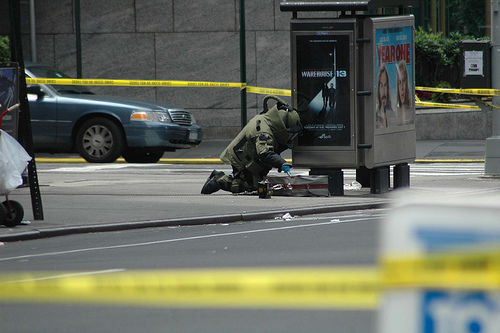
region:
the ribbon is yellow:
[25, 62, 296, 103]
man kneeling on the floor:
[194, 97, 328, 207]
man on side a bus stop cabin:
[194, 0, 428, 207]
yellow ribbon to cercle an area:
[0, 72, 499, 318]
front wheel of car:
[74, 110, 127, 170]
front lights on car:
[151, 107, 201, 129]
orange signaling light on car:
[125, 104, 155, 124]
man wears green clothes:
[199, 102, 314, 204]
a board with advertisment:
[360, 10, 422, 172]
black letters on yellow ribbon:
[23, 70, 290, 102]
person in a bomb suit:
[199, 93, 309, 208]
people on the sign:
[377, 56, 415, 128]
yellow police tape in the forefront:
[2, 249, 497, 321]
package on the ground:
[262, 167, 331, 204]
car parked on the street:
[22, 58, 207, 165]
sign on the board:
[287, 15, 354, 163]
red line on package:
[283, 180, 332, 189]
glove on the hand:
[267, 148, 287, 173]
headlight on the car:
[150, 107, 171, 126]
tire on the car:
[70, 110, 126, 166]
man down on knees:
[194, 88, 309, 203]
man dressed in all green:
[187, 90, 309, 196]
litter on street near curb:
[255, 205, 299, 223]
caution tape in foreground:
[4, 244, 499, 314]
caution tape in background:
[25, 66, 497, 106]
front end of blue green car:
[17, 59, 205, 162]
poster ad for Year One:
[370, 23, 418, 137]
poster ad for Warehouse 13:
[290, 28, 353, 154]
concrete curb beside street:
[2, 194, 393, 250]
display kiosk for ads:
[277, 4, 426, 194]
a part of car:
[11, 64, 215, 220]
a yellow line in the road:
[103, 251, 438, 326]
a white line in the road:
[194, 218, 301, 261]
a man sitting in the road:
[177, 81, 325, 222]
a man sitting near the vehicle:
[187, 65, 337, 227]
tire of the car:
[69, 110, 134, 191]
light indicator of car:
[124, 95, 163, 138]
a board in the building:
[461, 30, 498, 122]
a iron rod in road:
[10, 93, 60, 231]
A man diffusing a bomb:
[199, 94, 305, 199]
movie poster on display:
[364, 14, 424, 170]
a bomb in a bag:
[269, 168, 339, 200]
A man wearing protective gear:
[200, 94, 307, 208]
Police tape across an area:
[25, 60, 292, 105]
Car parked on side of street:
[5, 58, 208, 170]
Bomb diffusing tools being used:
[272, 157, 298, 179]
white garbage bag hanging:
[0, 126, 35, 200]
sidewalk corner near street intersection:
[53, 179, 375, 221]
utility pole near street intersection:
[455, 2, 498, 184]